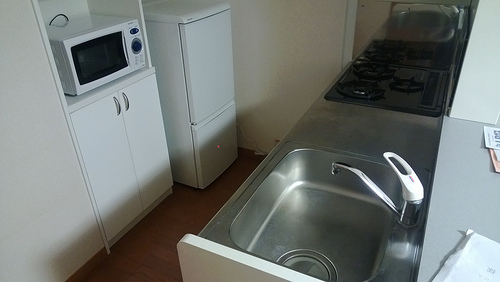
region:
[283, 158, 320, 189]
shine on the silver sink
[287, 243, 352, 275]
large hole in the silver sink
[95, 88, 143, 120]
silver doors on white cabinet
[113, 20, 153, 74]
black buttons on white microwave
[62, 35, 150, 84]
black door on white microwave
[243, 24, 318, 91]
white wall in the background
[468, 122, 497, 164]
paper laying on counter top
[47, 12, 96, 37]
black electrical cord behind microwave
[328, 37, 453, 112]
black stove counter top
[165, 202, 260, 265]
white edge of sink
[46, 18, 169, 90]
White microwave with black window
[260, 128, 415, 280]
small metal kitchen sink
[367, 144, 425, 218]
white faucet handle in kitchen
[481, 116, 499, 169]
papers are on the counter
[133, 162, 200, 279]
red brick floor in the kitchen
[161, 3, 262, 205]
small white fridge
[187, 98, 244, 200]
fridge has the freezer on the bottom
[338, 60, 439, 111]
three burner gas stove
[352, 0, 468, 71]
stainless steel wall with reflection of stove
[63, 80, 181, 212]
cupboard with handles at the top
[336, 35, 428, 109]
Black grills on the stove.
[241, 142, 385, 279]
Silver sink next to the stove.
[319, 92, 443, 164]
Counter space between the stove and the sink.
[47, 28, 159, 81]
White microwave on top of the small cabinet.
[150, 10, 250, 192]
Small refrigerator next to the microwave.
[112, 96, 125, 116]
Left silver handle on the cabinet door.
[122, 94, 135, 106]
Right silver handle on the cabinet door.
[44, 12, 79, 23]
Black wire behind the white microwave.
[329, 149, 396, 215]
Faucet on the silver sink.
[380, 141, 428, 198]
White faucet handle on the sink.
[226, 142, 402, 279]
the stainless steel kitchen sink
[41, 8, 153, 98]
a white microwave on a white shelf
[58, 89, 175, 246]
the cabinet under the microwave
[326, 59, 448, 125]
the stovetop next to the sink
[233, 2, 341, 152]
the wall next to the cabinet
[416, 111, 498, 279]
the counter above the sink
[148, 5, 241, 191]
the little fridge next to the microwave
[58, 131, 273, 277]
the floor below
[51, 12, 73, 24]
the cord behind the microwave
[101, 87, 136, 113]
the knobs on the cabinets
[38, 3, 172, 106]
white microwave in kitchen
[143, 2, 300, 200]
small refrigerator and freezer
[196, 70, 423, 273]
stainless steel sink in kitchen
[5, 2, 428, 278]
tiny rental kitchen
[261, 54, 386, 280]
stainless steel counter and sink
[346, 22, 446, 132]
small gas stove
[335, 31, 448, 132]
gas burners on stove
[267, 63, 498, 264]
kitchen counter with breakfast bar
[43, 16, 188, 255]
microwave above kitchen cabinets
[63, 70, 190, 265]
white kitchen cabinets with silver pulls